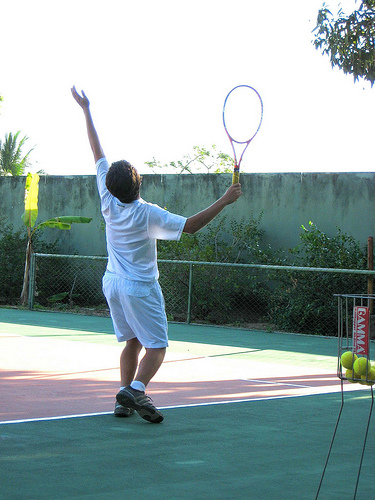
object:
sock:
[128, 380, 146, 391]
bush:
[260, 220, 367, 336]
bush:
[157, 210, 287, 322]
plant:
[18, 170, 92, 304]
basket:
[315, 293, 372, 498]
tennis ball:
[342, 368, 360, 385]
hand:
[65, 84, 91, 108]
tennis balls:
[353, 351, 369, 377]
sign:
[350, 305, 362, 357]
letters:
[355, 309, 363, 351]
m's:
[352, 323, 363, 343]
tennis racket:
[221, 83, 265, 184]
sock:
[120, 386, 124, 390]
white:
[357, 342, 361, 350]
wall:
[3, 173, 363, 356]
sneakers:
[112, 389, 135, 417]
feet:
[115, 385, 175, 423]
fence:
[32, 244, 357, 359]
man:
[49, 66, 275, 426]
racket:
[221, 85, 262, 186]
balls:
[339, 351, 357, 368]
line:
[3, 372, 336, 427]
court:
[2, 306, 363, 494]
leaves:
[22, 171, 90, 233]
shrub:
[255, 219, 362, 334]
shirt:
[95, 156, 184, 282]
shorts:
[101, 267, 170, 349]